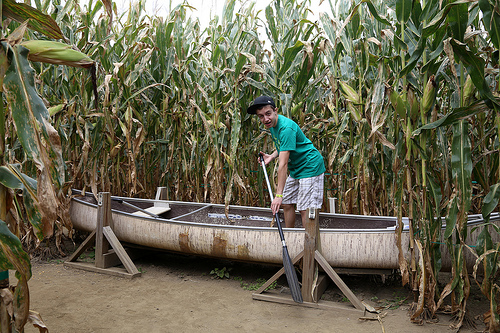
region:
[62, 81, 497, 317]
a person in a canoe in a corn field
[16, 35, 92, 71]
an ear of a corn on a corn stalk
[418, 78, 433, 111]
an ear of a corn on a corn stalk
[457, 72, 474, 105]
an ear of a corn on a corn stalk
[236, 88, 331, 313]
a person holding an oar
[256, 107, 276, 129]
the face of a person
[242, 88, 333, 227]
a man wearing a black cap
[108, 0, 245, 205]
several corn stalks in a corn field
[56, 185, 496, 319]
a canoe on wooden stands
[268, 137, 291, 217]
the arm of a man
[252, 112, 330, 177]
blue shirt on man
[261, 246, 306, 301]
black tip to oar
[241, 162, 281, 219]
white handle of oar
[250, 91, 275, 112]
black hat on head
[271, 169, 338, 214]
white and black shorts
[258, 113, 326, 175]
blue shirt on top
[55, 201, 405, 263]
small white boat in field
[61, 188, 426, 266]
small white boat on stilts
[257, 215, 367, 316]
wooden holding piece of boat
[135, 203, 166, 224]
white bench in boat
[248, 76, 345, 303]
boy standing in boat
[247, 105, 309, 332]
boy holding a paddle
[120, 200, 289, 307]
boat no in water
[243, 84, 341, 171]
boy wearing black hat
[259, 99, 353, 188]
boy wearing green shirt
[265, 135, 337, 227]
boy wearing plaid shorts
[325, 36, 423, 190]
tall stalks of corn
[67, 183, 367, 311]
boat on boat stand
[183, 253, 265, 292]
green plant growing under boat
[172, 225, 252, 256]
stains on side of boat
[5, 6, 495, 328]
a person in a canoe in a cornfield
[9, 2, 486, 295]
cornfield around a canoe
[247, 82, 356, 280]
a person standing in a canoe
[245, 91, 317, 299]
a person holding a paddle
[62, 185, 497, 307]
a canoe held up on wood supports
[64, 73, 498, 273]
a person with a paddle in a canoe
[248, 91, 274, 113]
a boy wearing a black hat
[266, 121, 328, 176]
a boy wearing a green shirt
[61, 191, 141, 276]
wooden platform used to hold a canoe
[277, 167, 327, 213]
a boy wearing shorts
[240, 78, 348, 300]
This is a person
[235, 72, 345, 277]
This is a person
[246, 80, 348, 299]
This is a person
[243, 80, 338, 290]
This is a person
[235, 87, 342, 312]
This is a person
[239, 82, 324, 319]
This is a person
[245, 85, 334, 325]
This is a person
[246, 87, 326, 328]
This is a person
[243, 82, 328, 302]
This is a person